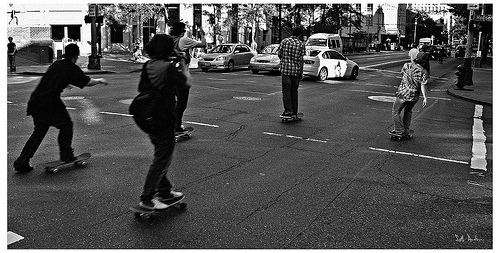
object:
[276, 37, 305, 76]
shirt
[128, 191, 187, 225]
board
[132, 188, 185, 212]
foot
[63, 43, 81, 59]
cap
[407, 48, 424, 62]
scarf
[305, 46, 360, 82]
car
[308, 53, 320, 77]
shadow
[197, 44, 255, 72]
automobile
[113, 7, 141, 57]
tree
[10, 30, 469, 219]
people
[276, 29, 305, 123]
person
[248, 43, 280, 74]
vehicle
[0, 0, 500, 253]
photo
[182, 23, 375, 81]
cars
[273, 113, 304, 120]
skateboarders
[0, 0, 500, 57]
buildings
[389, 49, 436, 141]
man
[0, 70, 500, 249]
road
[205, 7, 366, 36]
trees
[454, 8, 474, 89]
pole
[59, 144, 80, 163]
shoe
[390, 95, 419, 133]
trouser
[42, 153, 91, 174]
skateboard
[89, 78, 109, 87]
hand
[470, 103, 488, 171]
white lines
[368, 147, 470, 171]
white lines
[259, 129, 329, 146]
white lines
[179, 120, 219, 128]
white lines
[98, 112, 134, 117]
white lines